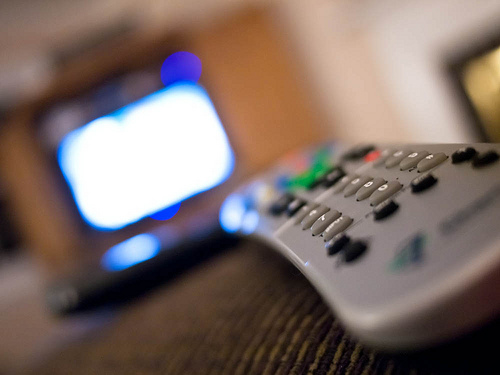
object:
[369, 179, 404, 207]
button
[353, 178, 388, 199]
button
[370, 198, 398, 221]
button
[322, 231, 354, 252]
button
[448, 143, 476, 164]
button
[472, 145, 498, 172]
button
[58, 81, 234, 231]
screen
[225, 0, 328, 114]
wall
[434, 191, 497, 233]
logo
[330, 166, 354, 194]
buttons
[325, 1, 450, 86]
wall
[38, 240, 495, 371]
pillow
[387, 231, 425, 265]
logo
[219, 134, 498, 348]
controller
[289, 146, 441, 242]
numbers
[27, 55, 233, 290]
entertainment system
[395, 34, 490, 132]
fireplace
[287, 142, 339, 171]
record button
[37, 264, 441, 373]
couch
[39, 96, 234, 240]
tv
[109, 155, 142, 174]
light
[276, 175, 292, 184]
buttons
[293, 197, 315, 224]
buttons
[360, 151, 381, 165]
buttons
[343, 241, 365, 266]
button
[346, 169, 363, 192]
button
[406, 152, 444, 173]
button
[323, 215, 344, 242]
button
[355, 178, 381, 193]
button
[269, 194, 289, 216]
button